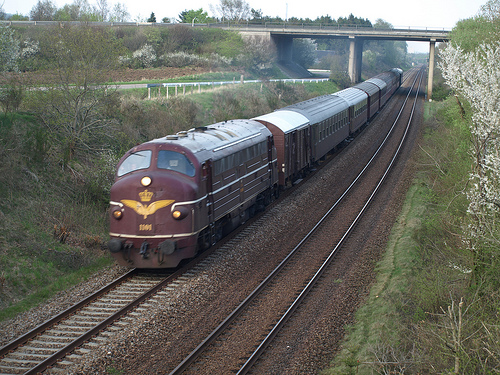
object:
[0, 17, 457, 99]
bridge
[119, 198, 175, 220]
bird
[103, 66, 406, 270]
train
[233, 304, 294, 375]
train tracks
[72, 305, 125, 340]
tracks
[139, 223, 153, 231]
1305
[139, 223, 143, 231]
numbers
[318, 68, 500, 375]
grass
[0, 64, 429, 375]
track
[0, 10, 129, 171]
trees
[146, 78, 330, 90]
gate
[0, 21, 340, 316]
grass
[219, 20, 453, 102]
bridge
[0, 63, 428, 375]
railroad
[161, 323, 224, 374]
tracks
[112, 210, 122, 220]
headlight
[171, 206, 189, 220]
headlight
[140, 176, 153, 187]
headlight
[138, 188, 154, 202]
crown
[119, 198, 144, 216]
wings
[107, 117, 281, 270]
engine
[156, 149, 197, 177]
window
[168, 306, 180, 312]
rocks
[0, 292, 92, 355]
railroad tracks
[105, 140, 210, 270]
front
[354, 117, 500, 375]
shrubbery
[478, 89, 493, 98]
blossoms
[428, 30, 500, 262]
tree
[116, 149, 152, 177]
window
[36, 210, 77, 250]
shrubbery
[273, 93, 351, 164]
train car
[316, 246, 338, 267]
train tracks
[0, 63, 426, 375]
gravel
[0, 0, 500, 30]
sky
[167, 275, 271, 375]
railroad tracks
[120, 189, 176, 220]
design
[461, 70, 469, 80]
blossoms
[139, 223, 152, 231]
number 1501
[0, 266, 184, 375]
train track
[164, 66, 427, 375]
train track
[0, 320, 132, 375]
cross tie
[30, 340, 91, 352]
cross tie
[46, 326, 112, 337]
cross tie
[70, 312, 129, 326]
cross tie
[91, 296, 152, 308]
cross tie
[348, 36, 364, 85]
support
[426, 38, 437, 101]
support